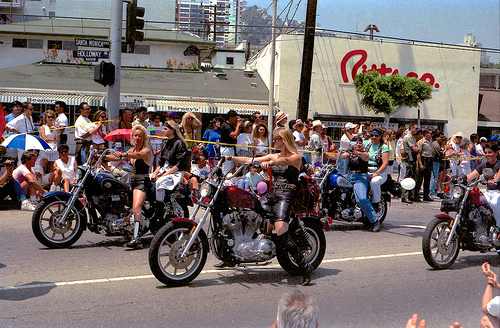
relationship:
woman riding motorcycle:
[222, 127, 315, 287] [148, 155, 326, 287]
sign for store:
[338, 49, 442, 89] [254, 33, 481, 110]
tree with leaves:
[353, 68, 434, 120] [354, 71, 433, 114]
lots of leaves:
[355, 68, 434, 115] [354, 71, 433, 114]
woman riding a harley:
[96, 124, 154, 250] [31, 145, 195, 250]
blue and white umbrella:
[1, 132, 53, 152] [1, 133, 51, 152]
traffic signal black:
[125, 1, 146, 44] [124, 1, 146, 44]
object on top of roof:
[364, 23, 382, 41] [249, 33, 482, 54]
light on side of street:
[106, 1, 145, 147] [0, 198, 499, 327]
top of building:
[1, 61, 274, 103] [1, 60, 276, 127]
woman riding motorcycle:
[96, 124, 154, 250] [31, 145, 195, 250]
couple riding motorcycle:
[316, 127, 391, 232] [321, 145, 388, 228]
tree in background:
[353, 68, 434, 120] [352, 68, 434, 126]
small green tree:
[353, 71, 432, 121] [353, 68, 434, 120]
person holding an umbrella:
[29, 149, 55, 185] [1, 133, 51, 152]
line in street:
[0, 251, 424, 291] [1, 201, 499, 327]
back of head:
[276, 287, 319, 327] [276, 288, 320, 327]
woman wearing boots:
[222, 127, 315, 287] [213, 229, 313, 287]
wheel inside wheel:
[157, 227, 204, 279] [148, 220, 211, 288]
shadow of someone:
[1, 280, 57, 301] [1, 260, 59, 301]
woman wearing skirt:
[96, 124, 154, 250] [129, 174, 154, 195]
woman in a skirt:
[222, 127, 315, 287] [258, 183, 297, 225]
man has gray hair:
[271, 285, 321, 327] [276, 287, 319, 327]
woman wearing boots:
[96, 124, 154, 250] [121, 220, 146, 249]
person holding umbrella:
[29, 149, 55, 185] [1, 133, 51, 152]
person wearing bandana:
[152, 119, 192, 222] [161, 120, 177, 131]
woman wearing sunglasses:
[222, 127, 315, 287] [270, 136, 284, 145]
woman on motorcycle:
[222, 127, 315, 287] [148, 155, 326, 287]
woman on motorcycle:
[96, 124, 154, 250] [31, 145, 195, 250]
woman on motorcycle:
[449, 139, 499, 230] [420, 174, 499, 269]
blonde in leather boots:
[222, 127, 315, 287] [213, 229, 313, 287]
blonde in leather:
[272, 127, 300, 155] [214, 184, 316, 286]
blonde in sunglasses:
[272, 127, 300, 155] [270, 136, 284, 145]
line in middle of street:
[0, 251, 424, 291] [0, 198, 499, 327]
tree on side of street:
[353, 68, 434, 120] [0, 198, 499, 327]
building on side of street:
[252, 31, 482, 143] [0, 198, 499, 327]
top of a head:
[280, 284, 317, 310] [276, 288, 320, 327]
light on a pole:
[106, 1, 145, 147] [106, 1, 121, 129]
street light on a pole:
[122, 1, 147, 54] [106, 1, 121, 129]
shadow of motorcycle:
[154, 266, 343, 290] [148, 155, 326, 287]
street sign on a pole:
[92, 59, 117, 87] [106, 1, 121, 129]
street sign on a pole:
[122, 1, 147, 55] [106, 1, 121, 129]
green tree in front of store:
[351, 69, 434, 123] [254, 33, 481, 110]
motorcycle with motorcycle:
[148, 155, 326, 287] [148, 137, 327, 287]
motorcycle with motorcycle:
[148, 137, 327, 287] [148, 137, 327, 287]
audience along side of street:
[1, 98, 499, 211] [1, 201, 499, 327]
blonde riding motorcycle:
[128, 125, 150, 150] [31, 145, 195, 250]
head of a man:
[276, 288, 320, 327] [271, 285, 321, 327]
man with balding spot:
[271, 285, 321, 327] [290, 298, 307, 309]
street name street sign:
[73, 35, 111, 49] [73, 37, 112, 49]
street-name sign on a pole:
[72, 49, 109, 60] [106, 1, 122, 133]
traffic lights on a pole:
[125, 1, 146, 44] [106, 1, 121, 129]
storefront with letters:
[279, 35, 481, 119] [339, 49, 435, 92]